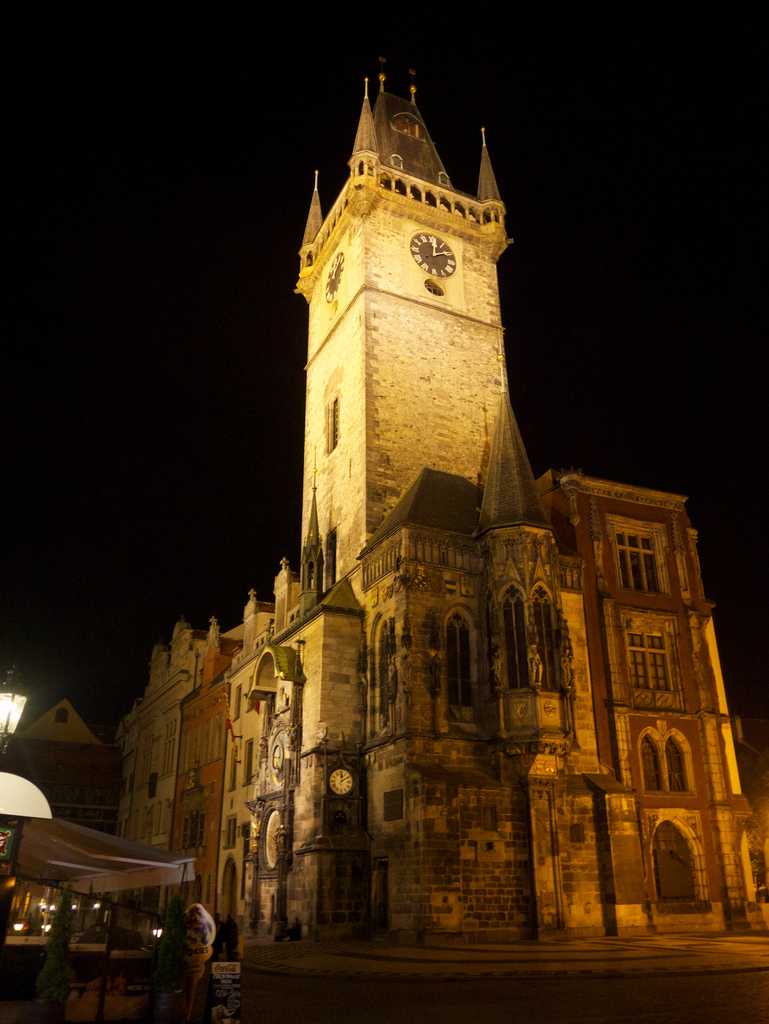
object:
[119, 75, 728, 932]
building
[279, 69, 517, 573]
tower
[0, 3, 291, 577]
sky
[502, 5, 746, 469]
sky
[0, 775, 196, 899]
tent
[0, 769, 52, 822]
light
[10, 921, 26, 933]
light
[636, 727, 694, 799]
window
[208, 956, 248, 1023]
sign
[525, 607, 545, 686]
statue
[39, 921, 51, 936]
lights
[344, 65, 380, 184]
turret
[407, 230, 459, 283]
clock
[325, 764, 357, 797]
clock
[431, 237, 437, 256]
white hand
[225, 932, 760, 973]
pavement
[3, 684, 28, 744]
light bar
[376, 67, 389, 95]
projection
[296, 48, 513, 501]
clock tower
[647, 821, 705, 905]
arch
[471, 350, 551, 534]
ornate spire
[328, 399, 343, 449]
window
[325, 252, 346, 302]
clock face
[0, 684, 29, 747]
street light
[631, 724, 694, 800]
arched windows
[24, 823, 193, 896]
awning